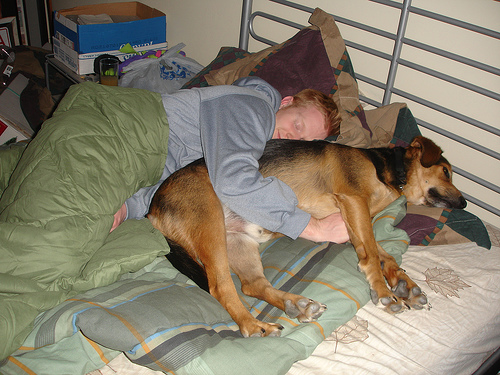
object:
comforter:
[94, 184, 497, 366]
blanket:
[0, 81, 172, 361]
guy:
[0, 75, 350, 245]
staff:
[70, 11, 115, 24]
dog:
[142, 135, 467, 339]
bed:
[0, 58, 498, 371]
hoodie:
[109, 76, 312, 242]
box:
[46, 1, 169, 76]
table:
[45, 43, 197, 89]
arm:
[193, 96, 319, 244]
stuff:
[60, 1, 162, 27]